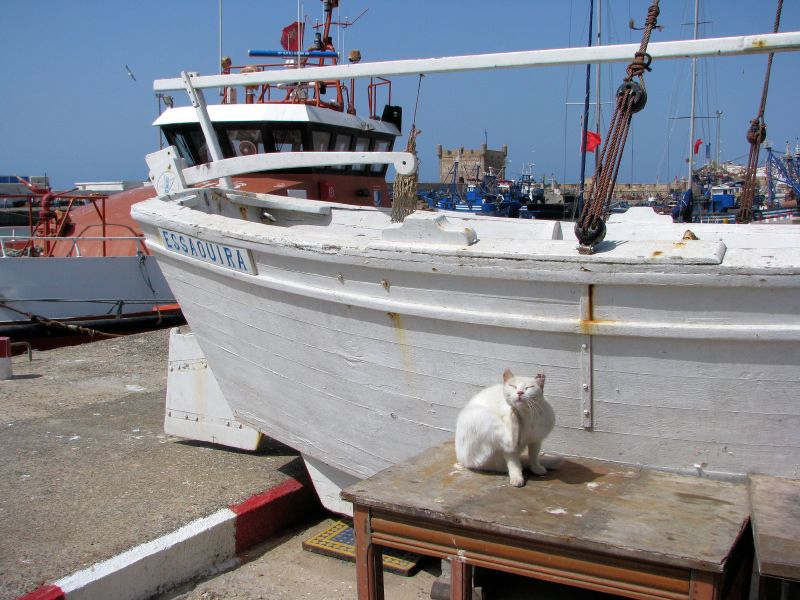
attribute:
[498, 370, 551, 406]
neck — blue, daytime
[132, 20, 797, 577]
boat — white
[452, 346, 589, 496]
cat — white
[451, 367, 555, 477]
cat — seated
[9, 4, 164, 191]
sky — clear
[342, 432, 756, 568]
table top — dirty